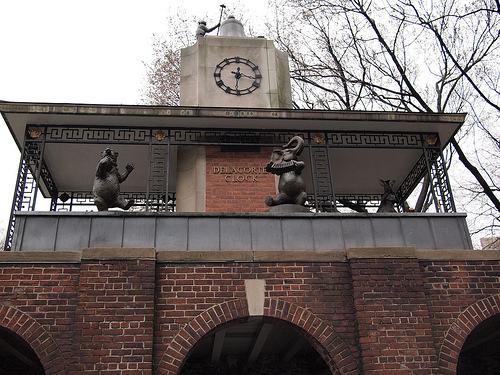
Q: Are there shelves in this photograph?
A: No, there are no shelves.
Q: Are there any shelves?
A: No, there are no shelves.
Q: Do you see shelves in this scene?
A: No, there are no shelves.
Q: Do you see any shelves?
A: No, there are no shelves.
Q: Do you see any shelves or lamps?
A: No, there are no shelves or lamps.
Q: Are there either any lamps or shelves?
A: No, there are no shelves or lamps.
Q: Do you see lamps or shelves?
A: No, there are no shelves or lamps.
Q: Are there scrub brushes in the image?
A: No, there are no scrub brushes.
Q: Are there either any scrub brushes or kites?
A: No, there are no scrub brushes or kites.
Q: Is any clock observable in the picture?
A: Yes, there is a clock.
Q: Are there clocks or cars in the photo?
A: Yes, there is a clock.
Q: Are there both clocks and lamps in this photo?
A: No, there is a clock but no lamps.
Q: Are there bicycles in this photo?
A: No, there are no bicycles.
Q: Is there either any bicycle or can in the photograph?
A: No, there are no bicycles or cans.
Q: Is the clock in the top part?
A: Yes, the clock is in the top of the image.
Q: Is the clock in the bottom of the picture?
A: No, the clock is in the top of the image.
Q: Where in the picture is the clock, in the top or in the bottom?
A: The clock is in the top of the image.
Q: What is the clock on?
A: The clock is on the clock tower.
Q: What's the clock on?
A: The clock is on the clock tower.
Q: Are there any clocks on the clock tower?
A: Yes, there is a clock on the clock tower.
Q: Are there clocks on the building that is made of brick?
A: Yes, there is a clock on the clock tower.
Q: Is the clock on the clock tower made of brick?
A: Yes, the clock is on the clock tower.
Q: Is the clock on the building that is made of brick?
A: Yes, the clock is on the clock tower.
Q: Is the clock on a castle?
A: No, the clock is on the clock tower.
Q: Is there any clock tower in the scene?
A: Yes, there is a clock tower.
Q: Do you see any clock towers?
A: Yes, there is a clock tower.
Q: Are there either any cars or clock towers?
A: Yes, there is a clock tower.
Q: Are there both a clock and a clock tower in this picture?
A: Yes, there are both a clock tower and a clock.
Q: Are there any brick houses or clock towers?
A: Yes, there is a brick clock tower.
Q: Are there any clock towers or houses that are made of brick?
A: Yes, the clock tower is made of brick.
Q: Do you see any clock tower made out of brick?
A: Yes, there is a clock tower that is made of brick.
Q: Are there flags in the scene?
A: No, there are no flags.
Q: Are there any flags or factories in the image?
A: No, there are no flags or factories.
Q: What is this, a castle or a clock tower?
A: This is a clock tower.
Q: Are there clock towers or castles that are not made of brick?
A: No, there is a clock tower but it is made of brick.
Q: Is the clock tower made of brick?
A: Yes, the clock tower is made of brick.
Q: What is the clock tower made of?
A: The clock tower is made of brick.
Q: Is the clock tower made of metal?
A: No, the clock tower is made of brick.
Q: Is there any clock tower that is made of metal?
A: No, there is a clock tower but it is made of brick.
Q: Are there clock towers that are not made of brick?
A: No, there is a clock tower but it is made of brick.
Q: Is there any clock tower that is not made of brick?
A: No, there is a clock tower but it is made of brick.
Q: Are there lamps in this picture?
A: No, there are no lamps.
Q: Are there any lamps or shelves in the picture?
A: No, there are no lamps or shelves.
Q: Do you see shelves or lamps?
A: No, there are no lamps or shelves.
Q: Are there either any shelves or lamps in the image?
A: No, there are no lamps or shelves.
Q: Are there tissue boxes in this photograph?
A: No, there are no tissue boxes.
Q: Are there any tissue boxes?
A: No, there are no tissue boxes.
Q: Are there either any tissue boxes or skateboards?
A: No, there are no tissue boxes or skateboards.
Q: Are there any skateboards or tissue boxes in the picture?
A: No, there are no tissue boxes or skateboards.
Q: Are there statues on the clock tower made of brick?
A: Yes, there is a statue on the clock tower.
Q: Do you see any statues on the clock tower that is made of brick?
A: Yes, there is a statue on the clock tower.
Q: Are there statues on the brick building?
A: Yes, there is a statue on the clock tower.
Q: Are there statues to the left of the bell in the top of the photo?
A: Yes, there is a statue to the left of the bell.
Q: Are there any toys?
A: No, there are no toys.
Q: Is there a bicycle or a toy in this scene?
A: No, there are no toys or bicycles.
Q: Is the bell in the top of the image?
A: Yes, the bell is in the top of the image.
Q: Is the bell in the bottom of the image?
A: No, the bell is in the top of the image.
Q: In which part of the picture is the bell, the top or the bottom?
A: The bell is in the top of the image.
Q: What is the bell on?
A: The bell is on the clock tower.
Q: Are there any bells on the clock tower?
A: Yes, there is a bell on the clock tower.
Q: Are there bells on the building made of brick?
A: Yes, there is a bell on the clock tower.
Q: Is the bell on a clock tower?
A: Yes, the bell is on a clock tower.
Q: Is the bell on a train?
A: No, the bell is on a clock tower.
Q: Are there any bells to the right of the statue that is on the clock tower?
A: Yes, there is a bell to the right of the statue.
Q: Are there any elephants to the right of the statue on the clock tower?
A: No, there is a bell to the right of the statue.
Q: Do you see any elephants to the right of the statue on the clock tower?
A: No, there is a bell to the right of the statue.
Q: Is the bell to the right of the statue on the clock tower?
A: Yes, the bell is to the right of the statue.